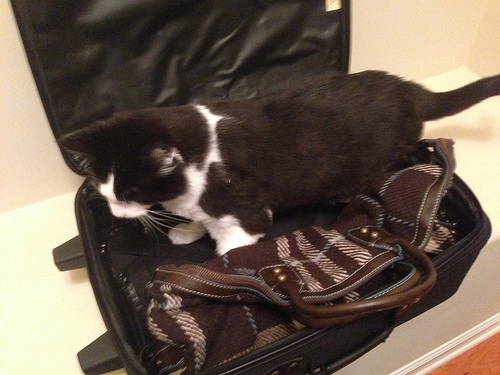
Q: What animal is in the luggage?
A: A cat.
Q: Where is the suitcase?
A: On a counter.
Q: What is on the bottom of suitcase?
A: Legs.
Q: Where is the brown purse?
A: In suitcase.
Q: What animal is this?
A: Cat.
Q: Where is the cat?
A: In the suitcase.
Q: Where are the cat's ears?
A: On its head.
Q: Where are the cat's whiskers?
A: On its face.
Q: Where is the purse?
A: By the suitcase.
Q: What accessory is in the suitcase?
A: Purse.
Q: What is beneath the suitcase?
A: A white table.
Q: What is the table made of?
A: Wood.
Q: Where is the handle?
A: On the suitcase.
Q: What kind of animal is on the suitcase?
A: Short haired cat.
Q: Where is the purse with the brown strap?
A: In front of the cat.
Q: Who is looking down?
A: The cat.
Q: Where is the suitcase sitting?
A: On a table.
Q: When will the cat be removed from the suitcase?
A: In five minutes.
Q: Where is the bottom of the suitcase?
A: To the left.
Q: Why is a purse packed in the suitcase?
A: To use on a trip.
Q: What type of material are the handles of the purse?
A: Leather.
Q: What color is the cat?
A: Black and white.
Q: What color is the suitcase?
A: Black.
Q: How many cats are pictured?
A: 1.